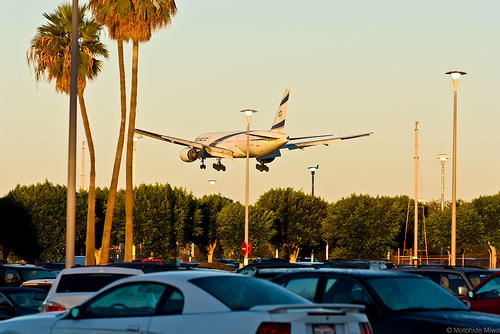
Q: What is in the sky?
A: An airplane.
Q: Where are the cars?
A: In a parking lot.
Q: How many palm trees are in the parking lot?
A: Three.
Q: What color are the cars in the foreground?
A: White and black.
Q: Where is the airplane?
A: In the air.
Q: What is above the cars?
A: An airplane.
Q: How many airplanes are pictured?
A: One.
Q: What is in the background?
A: Trees.